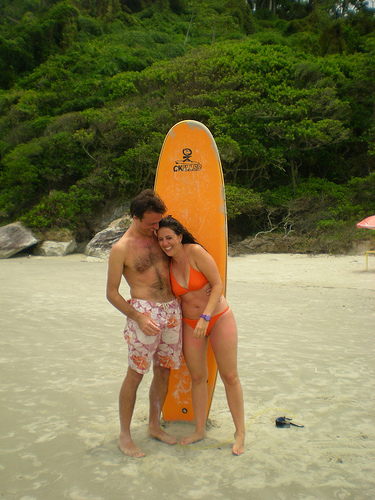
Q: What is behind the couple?
A: A surfboard.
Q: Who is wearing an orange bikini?
A: The woman.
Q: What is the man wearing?
A: Floral swimming trunks.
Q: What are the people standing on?
A: Sand.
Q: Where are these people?
A: On the beach.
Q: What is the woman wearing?
A: A bikini.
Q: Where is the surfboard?
A: Behind the people.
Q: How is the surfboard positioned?
A: Standing in the sand.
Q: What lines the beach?
A: The rocks.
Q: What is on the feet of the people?
A: Nothing.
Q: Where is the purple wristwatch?
A: On the wrist.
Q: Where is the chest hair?
A: On the chest.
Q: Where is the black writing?
A: On the surfboard.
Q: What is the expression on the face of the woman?
A: Happy.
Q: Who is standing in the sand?
A: A man and woman.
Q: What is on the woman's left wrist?
A: A purple watch.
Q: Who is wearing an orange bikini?
A: The woman.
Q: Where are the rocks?
A: At the edge of the sand.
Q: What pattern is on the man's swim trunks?
A: Flowers.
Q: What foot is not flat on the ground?
A: The woman's left foot.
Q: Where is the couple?
A: At the beach.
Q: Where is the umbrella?
A: Back right of the photo.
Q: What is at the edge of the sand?
A: Green foliage.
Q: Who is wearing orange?
A: The woman.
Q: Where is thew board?
A: Behind couple.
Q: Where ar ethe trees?
A: Hill.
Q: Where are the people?
A: Beach.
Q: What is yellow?
A: Surfboard.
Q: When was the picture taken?
A: Daytime.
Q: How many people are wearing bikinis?
A: One.